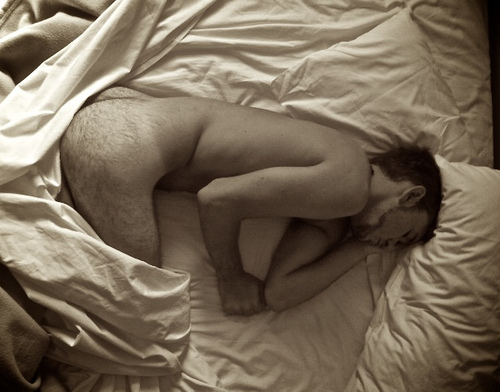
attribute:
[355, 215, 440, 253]
face — man's